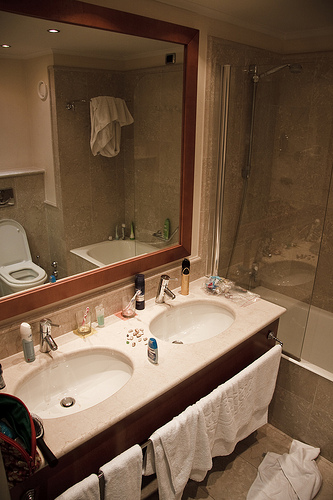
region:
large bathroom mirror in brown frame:
[2, 2, 200, 328]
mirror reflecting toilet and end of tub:
[0, 5, 183, 303]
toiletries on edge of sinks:
[0, 255, 282, 387]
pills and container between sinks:
[90, 317, 195, 383]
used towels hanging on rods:
[48, 341, 280, 489]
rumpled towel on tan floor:
[235, 437, 314, 489]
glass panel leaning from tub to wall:
[221, 26, 322, 364]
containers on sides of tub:
[94, 212, 173, 241]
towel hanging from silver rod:
[63, 82, 133, 156]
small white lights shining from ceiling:
[0, 8, 61, 52]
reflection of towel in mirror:
[78, 95, 139, 163]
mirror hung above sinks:
[3, 7, 218, 285]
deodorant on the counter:
[131, 313, 177, 408]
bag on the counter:
[1, 389, 72, 496]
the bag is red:
[6, 391, 62, 478]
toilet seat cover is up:
[1, 212, 49, 275]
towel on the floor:
[243, 426, 331, 493]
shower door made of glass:
[247, 52, 317, 368]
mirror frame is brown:
[18, 1, 221, 291]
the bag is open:
[0, 389, 52, 453]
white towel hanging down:
[66, 94, 134, 156]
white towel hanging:
[149, 346, 291, 492]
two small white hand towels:
[71, 444, 150, 498]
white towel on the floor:
[244, 436, 321, 498]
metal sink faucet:
[157, 277, 171, 305]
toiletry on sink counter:
[19, 319, 37, 363]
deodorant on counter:
[143, 336, 160, 365]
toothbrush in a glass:
[118, 291, 141, 319]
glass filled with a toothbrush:
[79, 299, 110, 331]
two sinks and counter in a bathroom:
[22, 273, 237, 428]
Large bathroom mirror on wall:
[5, 47, 178, 245]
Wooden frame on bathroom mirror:
[0, 18, 190, 256]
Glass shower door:
[234, 70, 313, 281]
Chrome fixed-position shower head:
[249, 58, 304, 86]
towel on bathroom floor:
[258, 436, 320, 499]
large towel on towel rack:
[152, 413, 276, 466]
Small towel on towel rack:
[104, 467, 135, 499]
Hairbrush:
[24, 411, 56, 467]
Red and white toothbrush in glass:
[72, 304, 92, 336]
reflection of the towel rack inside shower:
[84, 93, 132, 160]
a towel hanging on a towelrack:
[79, 92, 137, 159]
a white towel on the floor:
[239, 434, 327, 498]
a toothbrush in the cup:
[78, 301, 90, 339]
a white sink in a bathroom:
[142, 289, 239, 349]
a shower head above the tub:
[284, 57, 306, 77]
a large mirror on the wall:
[0, 1, 202, 331]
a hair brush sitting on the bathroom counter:
[28, 407, 64, 473]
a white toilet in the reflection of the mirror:
[1, 208, 51, 294]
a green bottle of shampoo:
[157, 216, 173, 247]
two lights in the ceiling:
[0, 24, 64, 58]